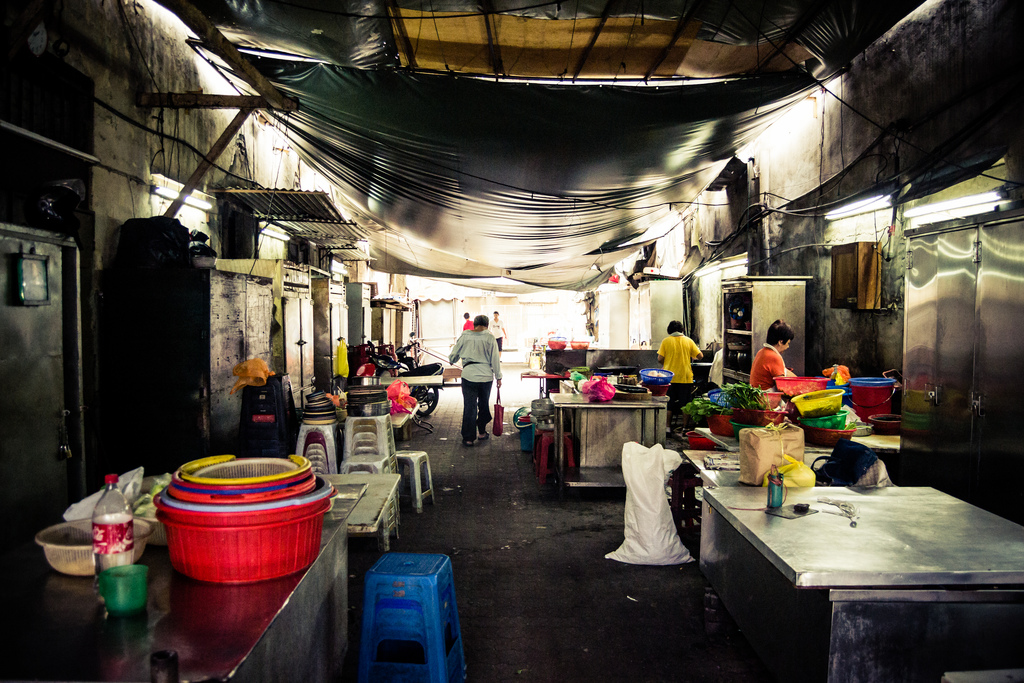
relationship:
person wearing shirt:
[446, 303, 509, 446] [435, 320, 526, 400]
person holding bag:
[446, 303, 509, 446] [474, 378, 520, 458]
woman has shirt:
[751, 319, 797, 394] [748, 350, 785, 385]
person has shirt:
[657, 320, 704, 437] [657, 339, 701, 381]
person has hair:
[657, 320, 704, 437] [660, 311, 687, 335]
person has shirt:
[447, 315, 504, 447] [450, 339, 509, 378]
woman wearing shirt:
[746, 318, 796, 394] [746, 338, 785, 390]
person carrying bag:
[447, 315, 504, 447] [487, 376, 505, 437]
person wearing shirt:
[655, 318, 703, 403] [653, 325, 701, 384]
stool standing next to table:
[351, 545, 470, 679] [3, 480, 375, 679]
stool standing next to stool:
[392, 441, 436, 511] [336, 444, 391, 470]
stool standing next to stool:
[336, 444, 391, 470] [290, 413, 340, 474]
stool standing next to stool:
[290, 413, 340, 474] [340, 405, 397, 458]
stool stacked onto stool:
[340, 405, 397, 458] [342, 426, 381, 450]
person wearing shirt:
[447, 315, 504, 447] [444, 323, 501, 384]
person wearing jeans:
[447, 315, 504, 447] [458, 374, 495, 444]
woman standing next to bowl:
[751, 319, 797, 394] [767, 372, 835, 394]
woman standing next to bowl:
[751, 319, 797, 394] [787, 387, 848, 418]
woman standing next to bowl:
[751, 319, 797, 394] [847, 370, 899, 388]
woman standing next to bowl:
[751, 319, 797, 394] [755, 387, 784, 409]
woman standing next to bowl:
[751, 319, 797, 394] [802, 405, 850, 427]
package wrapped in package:
[733, 413, 807, 483] [737, 416, 805, 485]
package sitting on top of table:
[733, 413, 807, 483] [681, 437, 833, 487]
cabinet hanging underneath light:
[828, 238, 887, 316] [821, 189, 893, 222]